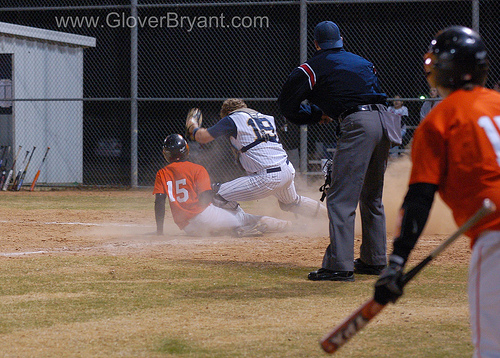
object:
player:
[152, 132, 303, 239]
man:
[148, 130, 304, 241]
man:
[289, 25, 497, 353]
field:
[0, 183, 500, 356]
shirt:
[405, 82, 497, 250]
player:
[370, 21, 497, 354]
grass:
[10, 178, 192, 210]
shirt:
[152, 159, 215, 228]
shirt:
[301, 46, 380, 117]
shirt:
[200, 107, 290, 178]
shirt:
[388, 104, 412, 142]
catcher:
[182, 94, 332, 240]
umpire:
[274, 20, 405, 282]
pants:
[316, 102, 395, 270]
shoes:
[350, 256, 384, 275]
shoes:
[305, 265, 358, 283]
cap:
[313, 22, 344, 50]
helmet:
[418, 22, 493, 92]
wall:
[0, 30, 98, 190]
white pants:
[468, 227, 499, 356]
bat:
[313, 198, 498, 356]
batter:
[322, 25, 499, 356]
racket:
[31, 145, 54, 187]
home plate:
[222, 233, 281, 238]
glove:
[182, 114, 201, 135]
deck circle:
[403, 304, 467, 346]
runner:
[156, 133, 279, 231]